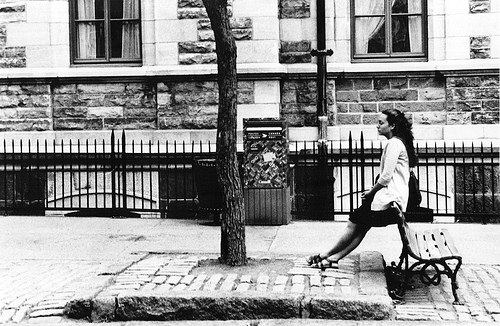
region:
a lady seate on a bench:
[316, 97, 439, 272]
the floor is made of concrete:
[169, 239, 317, 324]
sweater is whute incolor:
[381, 139, 418, 216]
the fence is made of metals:
[72, 119, 191, 226]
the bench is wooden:
[403, 214, 473, 302]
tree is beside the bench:
[192, 147, 234, 305]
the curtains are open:
[78, 1, 145, 71]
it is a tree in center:
[196, 3, 268, 265]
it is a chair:
[394, 200, 466, 315]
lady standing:
[309, 98, 431, 283]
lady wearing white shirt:
[354, 133, 411, 209]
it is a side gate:
[5, 135, 211, 227]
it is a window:
[345, 4, 437, 61]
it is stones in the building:
[14, 88, 169, 125]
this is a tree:
[200, 3, 265, 264]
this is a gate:
[2, 135, 492, 220]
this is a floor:
[0, 195, 487, 320]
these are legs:
[306, 215, 371, 270]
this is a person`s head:
[367, 100, 413, 140]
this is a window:
[350, 0, 427, 63]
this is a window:
[70, 0, 138, 65]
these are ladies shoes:
[307, 252, 332, 267]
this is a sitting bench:
[391, 196, 461, 293]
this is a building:
[1, 0, 494, 227]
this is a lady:
[332, 98, 423, 220]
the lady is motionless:
[313, 102, 411, 262]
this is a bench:
[405, 220, 461, 286]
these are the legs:
[302, 211, 372, 273]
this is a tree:
[204, 80, 264, 272]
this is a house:
[247, 7, 305, 104]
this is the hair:
[395, 120, 413, 134]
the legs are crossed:
[307, 235, 353, 270]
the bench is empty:
[399, 213, 456, 284]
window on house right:
[345, 2, 430, 62]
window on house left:
[51, 0, 151, 70]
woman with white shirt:
[392, 156, 404, 181]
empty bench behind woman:
[426, 241, 443, 253]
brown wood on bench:
[431, 228, 445, 240]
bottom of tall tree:
[211, 227, 257, 271]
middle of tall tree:
[206, 97, 246, 152]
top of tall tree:
[186, 1, 256, 33]